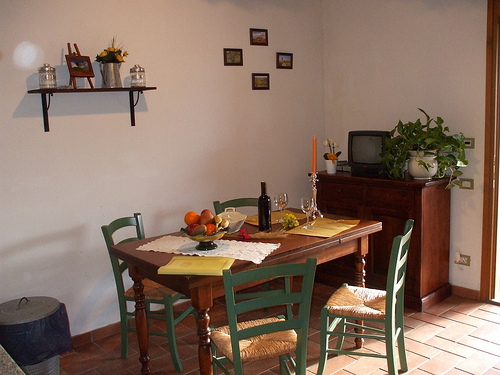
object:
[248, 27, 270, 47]
picture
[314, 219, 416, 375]
chair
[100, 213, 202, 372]
chair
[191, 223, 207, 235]
fruit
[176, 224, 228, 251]
basket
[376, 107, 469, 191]
plant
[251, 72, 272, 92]
picture frame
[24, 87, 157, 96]
shelf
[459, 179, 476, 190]
switch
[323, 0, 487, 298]
wall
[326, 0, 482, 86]
part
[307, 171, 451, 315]
cabinet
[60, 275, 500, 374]
floor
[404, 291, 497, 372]
part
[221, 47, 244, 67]
picture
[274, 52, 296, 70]
picture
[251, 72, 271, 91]
picture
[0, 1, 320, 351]
wall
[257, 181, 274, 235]
bottle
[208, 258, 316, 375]
chair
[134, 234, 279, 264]
placemat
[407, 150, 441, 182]
pot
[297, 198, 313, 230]
glass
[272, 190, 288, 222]
glass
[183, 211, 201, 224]
fruit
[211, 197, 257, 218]
chairs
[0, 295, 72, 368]
can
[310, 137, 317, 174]
candle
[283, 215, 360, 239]
placemat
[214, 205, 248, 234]
bowl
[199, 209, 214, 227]
fruit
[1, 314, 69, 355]
bag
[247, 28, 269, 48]
frame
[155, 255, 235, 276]
placemat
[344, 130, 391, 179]
tv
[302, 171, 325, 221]
candlestick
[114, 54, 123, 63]
flowers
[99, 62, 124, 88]
can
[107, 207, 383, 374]
table